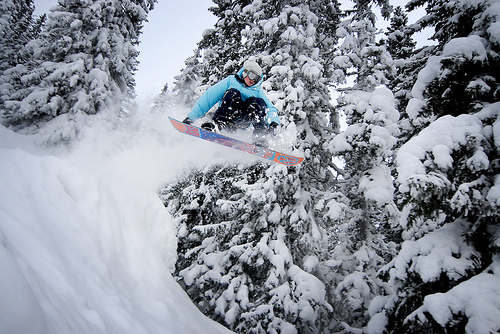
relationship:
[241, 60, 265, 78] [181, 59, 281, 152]
hat on snowboarder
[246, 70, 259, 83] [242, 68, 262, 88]
goggles on face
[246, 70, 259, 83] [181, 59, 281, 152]
goggles on snowboarder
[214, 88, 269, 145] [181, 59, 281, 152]
pants on snowboarder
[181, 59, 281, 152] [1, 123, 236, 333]
snowboarder on hill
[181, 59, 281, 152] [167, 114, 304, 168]
snowboarder on snowboard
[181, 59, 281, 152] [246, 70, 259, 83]
snowboarder wearing goggles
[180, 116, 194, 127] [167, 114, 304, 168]
hand on snowboard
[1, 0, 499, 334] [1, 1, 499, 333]
snow on trees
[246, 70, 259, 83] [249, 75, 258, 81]
goggles on eyes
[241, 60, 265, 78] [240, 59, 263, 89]
hat on head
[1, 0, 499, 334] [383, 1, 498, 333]
snow on tree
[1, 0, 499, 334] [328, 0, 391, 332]
snow on tree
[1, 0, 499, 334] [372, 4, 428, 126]
snow on tree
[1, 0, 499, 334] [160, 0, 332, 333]
snow on tree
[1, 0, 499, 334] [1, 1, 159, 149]
snow on tree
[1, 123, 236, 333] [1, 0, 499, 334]
hill made of snow